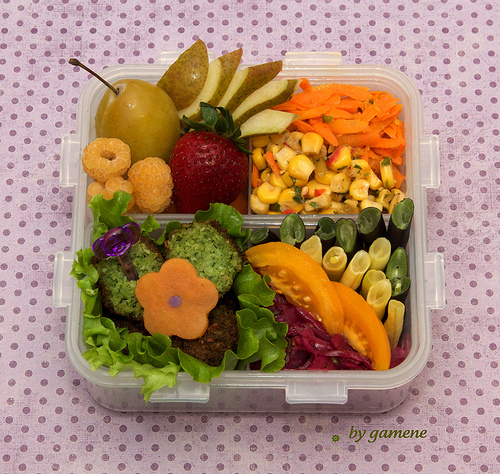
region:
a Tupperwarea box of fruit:
[64, 58, 446, 416]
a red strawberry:
[163, 102, 251, 216]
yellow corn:
[256, 130, 393, 220]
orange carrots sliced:
[300, 85, 403, 151]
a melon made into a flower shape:
[133, 257, 222, 340]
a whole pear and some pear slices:
[90, 40, 293, 157]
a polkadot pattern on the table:
[440, 332, 495, 458]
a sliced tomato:
[245, 240, 351, 330]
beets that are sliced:
[277, 315, 350, 367]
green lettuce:
[92, 332, 175, 370]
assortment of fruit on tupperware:
[66, 29, 298, 219]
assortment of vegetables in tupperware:
[87, 210, 430, 402]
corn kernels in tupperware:
[282, 145, 367, 204]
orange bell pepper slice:
[327, 272, 399, 374]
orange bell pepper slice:
[251, 243, 344, 335]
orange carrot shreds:
[297, 86, 402, 148]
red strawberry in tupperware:
[166, 99, 248, 203]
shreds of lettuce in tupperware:
[74, 298, 215, 386]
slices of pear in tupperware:
[154, 22, 316, 132]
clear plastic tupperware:
[276, 365, 428, 422]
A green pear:
[67, 53, 177, 158]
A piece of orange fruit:
[84, 130, 131, 178]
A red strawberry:
[172, 102, 253, 208]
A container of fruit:
[62, 53, 444, 409]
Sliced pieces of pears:
[155, 38, 298, 134]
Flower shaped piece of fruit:
[135, 259, 216, 339]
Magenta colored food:
[271, 291, 406, 373]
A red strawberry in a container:
[172, 104, 249, 211]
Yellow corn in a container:
[250, 132, 407, 207]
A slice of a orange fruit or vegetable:
[245, 239, 346, 336]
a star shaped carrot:
[132, 257, 220, 340]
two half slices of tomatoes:
[242, 227, 395, 367]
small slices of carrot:
[282, 82, 407, 184]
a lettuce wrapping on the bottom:
[71, 190, 288, 392]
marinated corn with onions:
[245, 116, 400, 219]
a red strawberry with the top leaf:
[155, 98, 263, 214]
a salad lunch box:
[50, 34, 442, 409]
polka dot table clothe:
[98, 0, 445, 60]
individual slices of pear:
[157, 26, 300, 146]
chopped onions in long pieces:
[242, 191, 415, 321]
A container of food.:
[49, 35, 444, 414]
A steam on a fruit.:
[67, 54, 117, 104]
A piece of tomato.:
[238, 236, 345, 343]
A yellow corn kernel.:
[283, 151, 318, 183]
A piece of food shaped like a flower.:
[131, 255, 221, 341]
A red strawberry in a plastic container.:
[164, 100, 254, 212]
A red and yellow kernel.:
[325, 141, 354, 171]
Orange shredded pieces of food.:
[272, 80, 405, 161]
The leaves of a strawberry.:
[178, 99, 253, 157]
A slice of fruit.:
[155, 36, 211, 111]